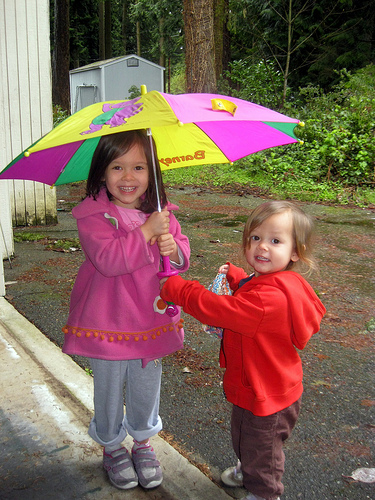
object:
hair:
[241, 199, 320, 280]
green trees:
[290, 61, 375, 187]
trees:
[218, 0, 375, 156]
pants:
[85, 357, 162, 448]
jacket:
[159, 261, 326, 416]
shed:
[68, 54, 165, 116]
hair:
[84, 128, 169, 214]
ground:
[0, 185, 375, 500]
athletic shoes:
[102, 446, 139, 490]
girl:
[61, 128, 191, 491]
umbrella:
[0, 85, 305, 318]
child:
[158, 196, 327, 500]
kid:
[159, 198, 326, 500]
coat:
[62, 184, 191, 367]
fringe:
[61, 318, 185, 343]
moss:
[311, 204, 374, 283]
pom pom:
[82, 327, 93, 340]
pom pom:
[92, 330, 99, 341]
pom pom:
[107, 333, 115, 345]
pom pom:
[113, 332, 125, 346]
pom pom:
[130, 332, 144, 347]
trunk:
[181, 0, 216, 94]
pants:
[228, 396, 300, 500]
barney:
[80, 95, 145, 135]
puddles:
[321, 220, 375, 289]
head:
[242, 198, 320, 280]